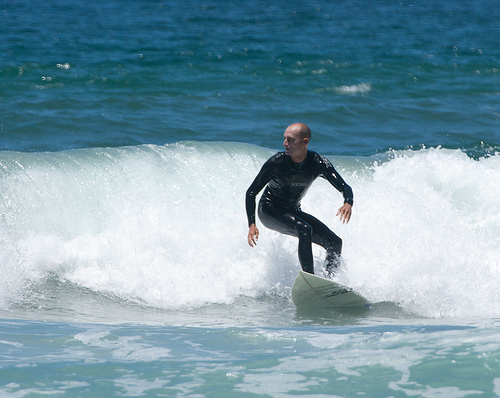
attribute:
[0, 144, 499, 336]
wave — big, foamy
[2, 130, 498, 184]
top — white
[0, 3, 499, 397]
ocean — dark blue, blue, ripply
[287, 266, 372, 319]
board — white, long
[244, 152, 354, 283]
suit — wet, rubber, shiny, black, part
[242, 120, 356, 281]
man — standing, balding, surfing, looking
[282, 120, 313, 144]
hair — very short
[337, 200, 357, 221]
hand — bare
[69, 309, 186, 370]
foam — white